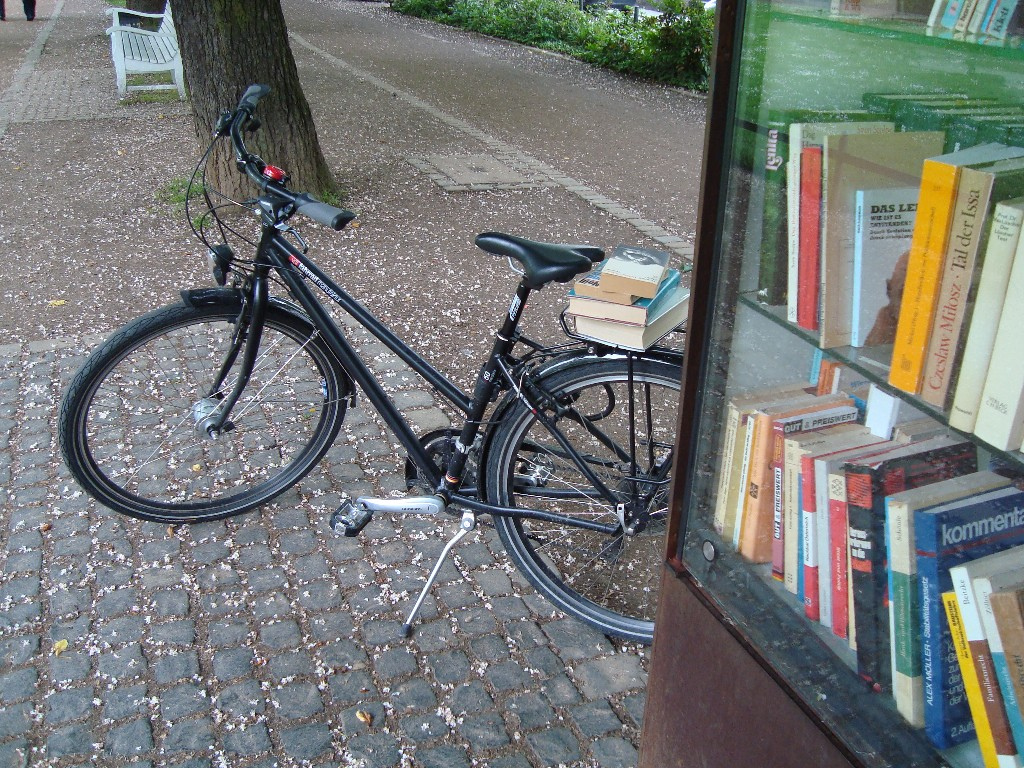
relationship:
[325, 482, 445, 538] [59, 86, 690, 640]
pedal on bicycle